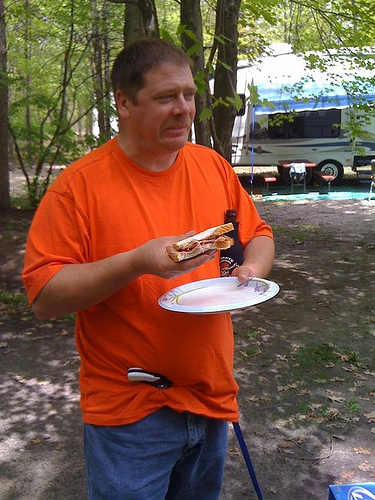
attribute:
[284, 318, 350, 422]
ground — brown, dead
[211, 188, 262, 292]
beer container — blue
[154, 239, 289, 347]
plate — white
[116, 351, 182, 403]
pistol — white handle grip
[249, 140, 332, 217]
picnic table — red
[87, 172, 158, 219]
orange tee shirt — mens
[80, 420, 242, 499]
blue denim pants — mens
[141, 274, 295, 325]
paper plate — round, flowered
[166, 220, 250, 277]
sandwich half eaten — half eaten